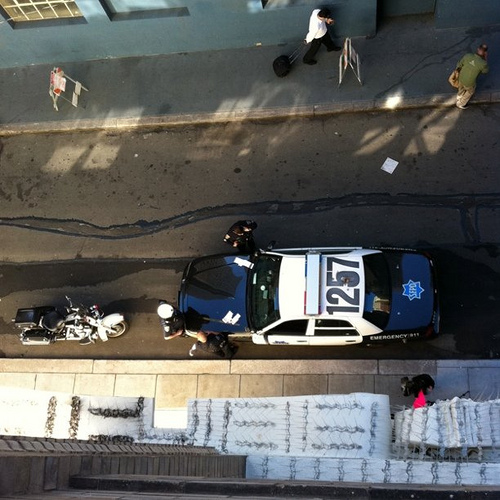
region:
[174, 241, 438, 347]
Police car on the street.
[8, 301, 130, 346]
Motorcycle behind the police car.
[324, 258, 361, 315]
Identifying number of police car.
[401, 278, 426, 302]
Identifying badge on the car.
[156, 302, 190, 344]
Police officer on the street.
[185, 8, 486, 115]
Men on the street.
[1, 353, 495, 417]
Sidewalk next to police car.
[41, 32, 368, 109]
Caution signs on the sidewalk.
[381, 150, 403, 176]
Paper in the street.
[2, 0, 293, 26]
Windows on the building.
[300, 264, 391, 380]
Cop car is number 1257.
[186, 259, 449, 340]
Cop car is white and black.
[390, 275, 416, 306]
Blue star logo on back of car.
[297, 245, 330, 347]
Lights on top of car.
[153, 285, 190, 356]
Person wearing white helmet.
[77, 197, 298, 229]
Black tar patch in road.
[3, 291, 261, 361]
Motorcycle near police car.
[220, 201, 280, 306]
Policeman near car.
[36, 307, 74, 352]
Black seat on bike.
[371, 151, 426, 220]
White garbage on ground.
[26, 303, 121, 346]
this is a motorbike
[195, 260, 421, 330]
this is a car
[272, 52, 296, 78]
this is a bag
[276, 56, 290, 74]
the bag is black in color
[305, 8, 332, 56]
this is a man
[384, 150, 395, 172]
this is a paper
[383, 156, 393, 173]
the paper is white in color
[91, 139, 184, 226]
this is a road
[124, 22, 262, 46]
this is a wall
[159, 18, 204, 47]
the wall is blue in color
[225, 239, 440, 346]
this is a police cab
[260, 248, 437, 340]
the cab is black and white in color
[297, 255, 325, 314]
this is a siren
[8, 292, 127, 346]
this is a motorbike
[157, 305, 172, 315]
this is a helmet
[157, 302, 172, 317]
the helmet is white in color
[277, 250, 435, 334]
the cab is parked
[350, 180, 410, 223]
the road is cracked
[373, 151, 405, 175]
a paper on the road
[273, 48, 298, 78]
this is a suitcase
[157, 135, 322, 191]
this is the road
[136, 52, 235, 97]
this is the pavement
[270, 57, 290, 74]
the suitcase is black in color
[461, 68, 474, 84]
the t-shirt is green in color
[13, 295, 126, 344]
this is a motorcycle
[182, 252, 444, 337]
this is a police car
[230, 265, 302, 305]
the car is black and white in color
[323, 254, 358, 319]
a four-digit number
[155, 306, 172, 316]
this is a white helmet